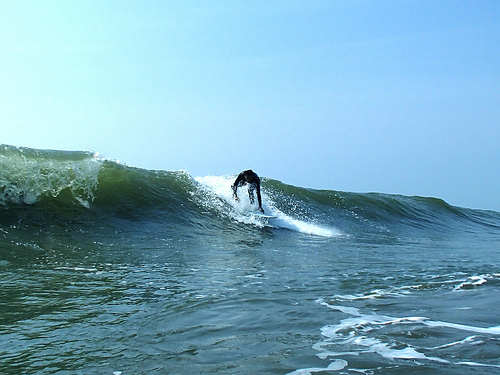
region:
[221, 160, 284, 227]
A person on a white surfboard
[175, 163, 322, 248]
A person surfing on a wave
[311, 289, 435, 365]
white foam on blue water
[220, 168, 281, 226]
A person in a dark colored wetsuit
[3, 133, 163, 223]
A curling, blue ocean wave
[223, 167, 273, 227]
A person in a wetsuit bending down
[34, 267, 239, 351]
Blue ocean water with foam dots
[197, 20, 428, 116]
Cloudless, pristine blue sky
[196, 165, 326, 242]
A person surfing atop white ocean foam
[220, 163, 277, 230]
a man surfing inb a wet suit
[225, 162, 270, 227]
man surfing on a wave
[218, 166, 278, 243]
man just standing up on board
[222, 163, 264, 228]
man standing on board on a wave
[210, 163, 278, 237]
man going down face of wave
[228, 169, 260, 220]
wetsuit on a man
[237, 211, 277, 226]
short board on a wave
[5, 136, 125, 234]
breaking section of wave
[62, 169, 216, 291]
face of the wave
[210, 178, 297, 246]
white water from surf board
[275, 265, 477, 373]
foamy water by wave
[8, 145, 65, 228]
This is a tide of water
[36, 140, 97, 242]
This is a tide of water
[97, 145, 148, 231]
This is a tide of water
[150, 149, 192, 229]
This is a tide of water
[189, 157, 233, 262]
This is a tide of water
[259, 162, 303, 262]
This is a tide of water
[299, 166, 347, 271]
This is a tide of water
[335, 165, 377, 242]
This is a tide of water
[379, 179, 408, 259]
This is a tide of water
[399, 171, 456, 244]
This is a tide of water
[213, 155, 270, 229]
surfer in ocean water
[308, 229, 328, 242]
white water splashing up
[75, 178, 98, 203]
white water splashing up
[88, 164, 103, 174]
white water splashing up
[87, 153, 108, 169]
white water splashing up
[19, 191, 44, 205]
white water splashing up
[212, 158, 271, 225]
surfer in black wetsuit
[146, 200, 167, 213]
ripple in the ocean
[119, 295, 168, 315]
ripple in the ocean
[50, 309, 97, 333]
ripple in the ocean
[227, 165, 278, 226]
surfer crouched on surfboard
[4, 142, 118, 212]
crest of wave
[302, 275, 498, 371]
white foam in calm part of ocean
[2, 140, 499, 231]
wave surfer is riding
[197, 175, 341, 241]
white foam surfer is making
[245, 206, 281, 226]
white tip of surfboard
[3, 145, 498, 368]
ocean surfboarder is in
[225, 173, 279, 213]
black wetsuit of surfer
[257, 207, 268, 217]
surfer's hand touching board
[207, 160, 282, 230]
surfboarder trying to ride a wave